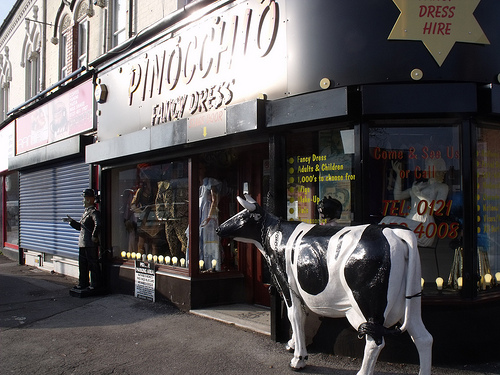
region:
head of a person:
[78, 178, 119, 212]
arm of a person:
[59, 212, 91, 235]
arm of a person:
[89, 217, 114, 237]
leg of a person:
[70, 259, 93, 284]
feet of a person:
[60, 284, 90, 299]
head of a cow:
[194, 178, 289, 260]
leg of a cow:
[273, 305, 315, 356]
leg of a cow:
[343, 316, 399, 373]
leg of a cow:
[388, 303, 453, 373]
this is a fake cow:
[188, 181, 432, 373]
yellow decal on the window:
[276, 145, 356, 220]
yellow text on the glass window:
[280, 135, 362, 222]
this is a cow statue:
[201, 180, 449, 373]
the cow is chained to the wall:
[202, 178, 466, 374]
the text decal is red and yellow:
[367, 133, 473, 255]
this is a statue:
[45, 175, 114, 302]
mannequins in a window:
[122, 166, 239, 278]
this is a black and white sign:
[127, 250, 164, 307]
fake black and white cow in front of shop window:
[217, 182, 433, 374]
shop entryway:
[188, 141, 271, 336]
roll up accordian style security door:
[7, 133, 93, 260]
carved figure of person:
[64, 189, 99, 299]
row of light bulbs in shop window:
[120, 251, 218, 271]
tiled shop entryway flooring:
[188, 300, 271, 332]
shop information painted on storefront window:
[286, 154, 357, 225]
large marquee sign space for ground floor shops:
[3, 2, 499, 175]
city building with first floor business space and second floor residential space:
[1, 0, 499, 373]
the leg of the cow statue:
[271, 271, 310, 366]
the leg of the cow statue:
[283, 304, 300, 351]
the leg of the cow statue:
[352, 301, 383, 373]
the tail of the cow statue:
[392, 226, 417, 333]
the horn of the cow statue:
[236, 193, 256, 210]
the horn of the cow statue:
[242, 191, 253, 203]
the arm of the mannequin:
[62, 212, 82, 233]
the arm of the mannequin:
[89, 209, 103, 239]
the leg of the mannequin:
[74, 243, 89, 290]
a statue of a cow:
[201, 184, 446, 374]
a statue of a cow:
[206, 185, 421, 373]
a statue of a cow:
[199, 182, 456, 373]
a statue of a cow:
[197, 180, 442, 373]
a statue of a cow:
[199, 174, 399, 372]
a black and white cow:
[209, 192, 446, 367]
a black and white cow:
[202, 180, 431, 362]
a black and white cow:
[196, 182, 456, 367]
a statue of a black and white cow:
[212, 185, 443, 372]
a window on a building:
[96, 168, 189, 270]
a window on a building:
[191, 156, 257, 276]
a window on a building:
[278, 131, 353, 226]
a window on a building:
[362, 120, 459, 287]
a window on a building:
[474, 125, 498, 280]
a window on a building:
[18, 59, 33, 107]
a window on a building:
[27, 47, 43, 87]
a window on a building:
[53, 26, 72, 78]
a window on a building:
[73, 22, 84, 65]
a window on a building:
[2, 172, 22, 249]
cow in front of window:
[213, 190, 434, 373]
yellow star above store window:
[388, 0, 491, 66]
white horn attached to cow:
[234, 196, 254, 213]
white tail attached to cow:
[391, 228, 418, 334]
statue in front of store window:
[61, 186, 103, 298]